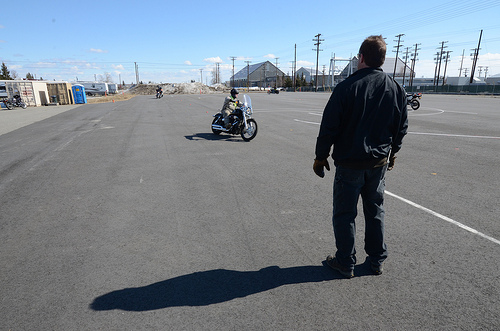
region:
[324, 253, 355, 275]
man standing wearing shoe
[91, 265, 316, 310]
shadow of man falling on ground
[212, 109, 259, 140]
black color motor cycle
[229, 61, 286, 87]
building visible at background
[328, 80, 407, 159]
man wearing jacket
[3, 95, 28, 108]
parked bike at distance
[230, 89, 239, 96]
man wearing helmet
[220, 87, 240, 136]
man riding bike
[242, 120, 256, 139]
front wheel of the bike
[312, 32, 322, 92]
erected pole with wires moving on it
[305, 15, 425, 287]
this person is standing on asphalt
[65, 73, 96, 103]
this is a blue portapotty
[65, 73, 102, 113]
this port-a-potty is blue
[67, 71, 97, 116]
the roof of the port-a-potty is white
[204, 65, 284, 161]
a man on a motorcycle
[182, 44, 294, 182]
this person is on a motorcycle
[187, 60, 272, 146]
the motorcycle is stationary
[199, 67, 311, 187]
the motorcycle is not moving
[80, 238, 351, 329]
a shadow of a man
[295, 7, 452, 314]
he is wearing gloves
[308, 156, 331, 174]
left hand of man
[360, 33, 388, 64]
the man's brown hair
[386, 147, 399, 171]
right hand of the man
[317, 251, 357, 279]
the man's left foot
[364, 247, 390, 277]
the man's right foot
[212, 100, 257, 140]
motorcycle being ridden in street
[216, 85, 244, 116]
man riding motorcycle outside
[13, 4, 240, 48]
the clear blue sky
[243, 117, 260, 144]
front tire on black bike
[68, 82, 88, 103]
portable potty on the ground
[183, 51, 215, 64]
a cloud in the sky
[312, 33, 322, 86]
a telephone pole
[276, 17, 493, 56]
wires on the telephone pole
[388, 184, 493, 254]
white lines on the street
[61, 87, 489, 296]
pavement on the street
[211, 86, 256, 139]
a person riding a motorcycle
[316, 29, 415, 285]
a person standing on the street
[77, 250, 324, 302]
the shadow of the man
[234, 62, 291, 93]
a building in the background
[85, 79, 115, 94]
a white trailer in the background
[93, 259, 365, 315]
A shadow on the ground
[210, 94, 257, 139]
A motorcycle on the road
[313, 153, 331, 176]
The man is wearing a glove on his left hand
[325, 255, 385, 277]
The man is wearing shoes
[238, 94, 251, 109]
A windshield on the motorcycle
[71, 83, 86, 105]
A portable toilet by the motorcycle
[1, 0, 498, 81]
The sky above the motorcycle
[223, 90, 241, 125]
A man sitting on the motorcycle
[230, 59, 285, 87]
A building behind the motorcycles